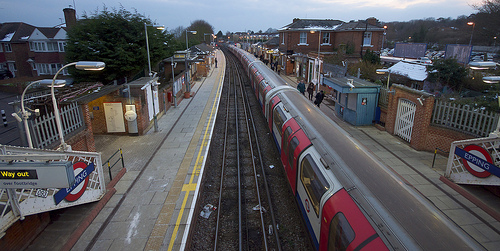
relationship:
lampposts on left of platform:
[16, 50, 130, 181] [24, 48, 225, 248]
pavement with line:
[0, 43, 499, 250] [166, 50, 225, 250]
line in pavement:
[166, 50, 225, 250] [0, 43, 499, 250]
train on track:
[223, 38, 485, 248] [223, 74, 274, 249]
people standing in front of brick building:
[236, 38, 286, 78] [276, 16, 385, 57]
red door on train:
[276, 117, 312, 197] [223, 38, 485, 248]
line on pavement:
[166, 50, 225, 250] [27, 49, 225, 249]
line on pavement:
[166, 50, 225, 250] [282, 70, 497, 248]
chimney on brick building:
[62, 8, 79, 28] [0, 8, 77, 79]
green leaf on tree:
[163, 34, 173, 44] [65, 7, 173, 94]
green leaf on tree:
[123, 34, 135, 44] [65, 7, 173, 94]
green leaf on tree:
[110, 27, 120, 39] [65, 7, 173, 94]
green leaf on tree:
[130, 60, 140, 71] [65, 7, 173, 94]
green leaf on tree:
[76, 32, 83, 43] [65, 7, 173, 94]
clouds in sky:
[247, 7, 332, 23] [121, 3, 378, 25]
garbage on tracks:
[198, 202, 213, 221] [225, 65, 253, 246]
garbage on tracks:
[268, 222, 280, 234] [225, 65, 253, 246]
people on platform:
[237, 23, 366, 131] [281, 66, 403, 177]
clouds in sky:
[306, 0, 465, 15] [12, 0, 492, 17]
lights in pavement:
[455, 18, 485, 48] [0, 43, 499, 250]